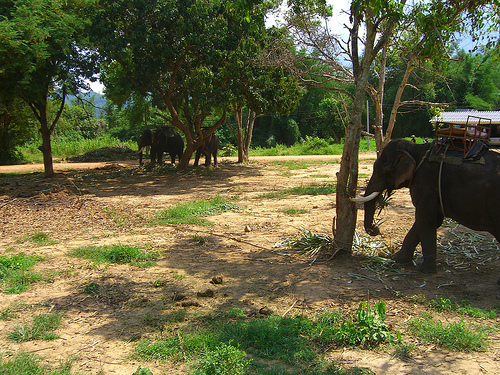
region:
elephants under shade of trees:
[18, 5, 494, 365]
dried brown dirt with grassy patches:
[10, 160, 475, 362]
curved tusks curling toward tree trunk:
[335, 145, 380, 210]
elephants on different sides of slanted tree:
[125, 95, 220, 170]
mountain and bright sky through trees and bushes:
[50, 40, 151, 125]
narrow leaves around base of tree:
[270, 220, 386, 275]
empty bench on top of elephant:
[405, 106, 492, 226]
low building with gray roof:
[427, 105, 494, 146]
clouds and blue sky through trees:
[260, 0, 495, 72]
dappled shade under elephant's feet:
[55, 150, 261, 205]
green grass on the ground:
[256, 301, 375, 373]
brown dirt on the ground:
[254, 257, 304, 303]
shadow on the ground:
[181, 236, 268, 337]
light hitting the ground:
[126, 203, 184, 241]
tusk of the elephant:
[353, 180, 388, 215]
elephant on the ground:
[352, 115, 489, 245]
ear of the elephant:
[384, 150, 419, 193]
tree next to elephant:
[313, 129, 368, 216]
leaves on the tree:
[135, 26, 234, 101]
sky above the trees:
[326, 3, 353, 40]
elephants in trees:
[6, 1, 300, 183]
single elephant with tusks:
[127, 124, 190, 171]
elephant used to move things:
[343, 98, 488, 285]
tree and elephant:
[265, 8, 446, 269]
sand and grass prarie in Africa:
[10, 179, 285, 365]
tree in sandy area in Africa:
[0, 19, 103, 192]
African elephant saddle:
[413, 104, 498, 179]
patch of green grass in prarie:
[76, 229, 156, 276]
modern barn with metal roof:
[420, 102, 499, 147]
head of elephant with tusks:
[352, 132, 419, 245]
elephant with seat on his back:
[347, 99, 493, 267]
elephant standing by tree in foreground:
[332, 15, 497, 276]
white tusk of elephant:
[347, 187, 375, 209]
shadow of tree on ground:
[60, 223, 352, 317]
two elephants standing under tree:
[114, 123, 214, 181]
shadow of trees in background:
[52, 148, 259, 200]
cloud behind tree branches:
[265, 0, 382, 64]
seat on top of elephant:
[425, 106, 487, 142]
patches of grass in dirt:
[14, 184, 475, 369]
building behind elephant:
[428, 101, 498, 138]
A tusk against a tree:
[349, 195, 369, 202]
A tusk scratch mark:
[350, 185, 355, 190]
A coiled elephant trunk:
[361, 221, 376, 233]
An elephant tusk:
[356, 195, 376, 200]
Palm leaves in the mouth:
[378, 193, 386, 208]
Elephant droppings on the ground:
[196, 272, 223, 299]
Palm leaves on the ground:
[357, 238, 384, 259]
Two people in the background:
[409, 133, 431, 145]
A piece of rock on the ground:
[243, 224, 252, 234]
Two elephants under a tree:
[133, 121, 219, 166]